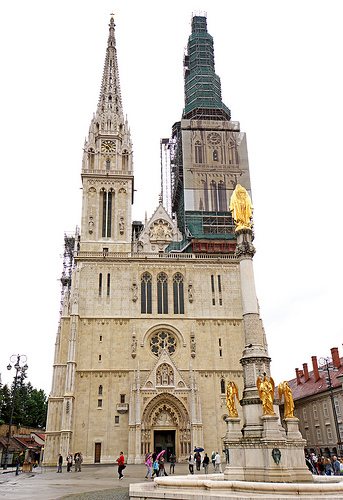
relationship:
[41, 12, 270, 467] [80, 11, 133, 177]
boulding has spire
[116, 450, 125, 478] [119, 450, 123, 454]
man has head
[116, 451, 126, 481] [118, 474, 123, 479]
man has foot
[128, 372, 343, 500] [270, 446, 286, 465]
fountain has head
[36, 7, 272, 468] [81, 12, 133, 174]
boulding has spire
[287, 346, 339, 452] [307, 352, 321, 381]
building has chimney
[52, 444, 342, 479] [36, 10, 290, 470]
people front building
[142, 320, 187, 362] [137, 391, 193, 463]
circular window above doorway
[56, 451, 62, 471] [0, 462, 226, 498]
person walking in court yard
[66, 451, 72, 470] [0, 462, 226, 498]
person walking in court yard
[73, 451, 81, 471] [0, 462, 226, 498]
person walking in court yard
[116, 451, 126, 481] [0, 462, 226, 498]
man walking in court yard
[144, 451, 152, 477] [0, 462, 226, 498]
person walking in court yard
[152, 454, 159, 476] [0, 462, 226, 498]
person walking in court yard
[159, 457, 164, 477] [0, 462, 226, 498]
person walking in court yard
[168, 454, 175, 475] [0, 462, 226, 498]
person walking in court yard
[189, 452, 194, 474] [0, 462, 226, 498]
person walking in court yard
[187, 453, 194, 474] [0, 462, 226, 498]
person walking in court yard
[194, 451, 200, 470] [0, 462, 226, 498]
person walking in court yard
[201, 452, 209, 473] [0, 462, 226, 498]
person walking in court yard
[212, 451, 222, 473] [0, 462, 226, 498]
person walking in court yard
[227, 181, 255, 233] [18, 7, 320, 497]
statue on building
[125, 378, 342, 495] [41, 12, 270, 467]
fountain near boulding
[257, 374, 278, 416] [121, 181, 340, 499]
statue on fountain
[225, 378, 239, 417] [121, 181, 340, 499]
statue on fountain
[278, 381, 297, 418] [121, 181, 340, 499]
statue on fountain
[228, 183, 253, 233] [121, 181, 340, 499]
statue on fountain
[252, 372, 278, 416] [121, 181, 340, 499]
statue on fountain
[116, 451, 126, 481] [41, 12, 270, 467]
man in front of boulding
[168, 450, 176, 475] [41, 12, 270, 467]
person in front of boulding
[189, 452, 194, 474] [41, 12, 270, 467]
person in front of boulding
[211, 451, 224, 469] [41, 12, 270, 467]
person in front of boulding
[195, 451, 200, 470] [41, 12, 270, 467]
person in front of boulding